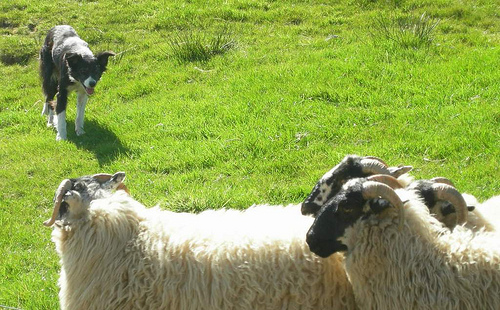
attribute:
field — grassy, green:
[108, 2, 494, 182]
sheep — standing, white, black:
[42, 166, 341, 308]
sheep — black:
[304, 172, 498, 300]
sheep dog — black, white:
[36, 22, 116, 144]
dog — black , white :
[38, 16, 114, 142]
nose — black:
[87, 78, 95, 87]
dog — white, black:
[27, 17, 119, 144]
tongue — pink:
[86, 87, 94, 94]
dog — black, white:
[32, 18, 112, 143]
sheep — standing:
[307, 183, 494, 308]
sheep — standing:
[303, 154, 498, 264]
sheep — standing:
[416, 169, 498, 229]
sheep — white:
[31, 147, 467, 307]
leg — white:
[73, 87, 89, 138]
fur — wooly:
[41, 162, 498, 308]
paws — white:
[54, 125, 86, 144]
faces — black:
[307, 173, 369, 266]